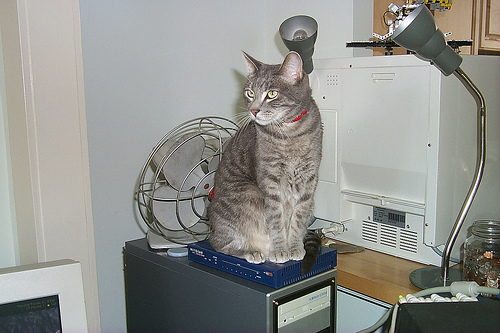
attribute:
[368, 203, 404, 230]
plate — silver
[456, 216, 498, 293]
jar — clear, glass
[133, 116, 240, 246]
fan — gray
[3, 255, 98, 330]
frame — laminated, white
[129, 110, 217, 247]
fan — small, dusty, old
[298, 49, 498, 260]
machine — large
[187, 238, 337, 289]
component — blue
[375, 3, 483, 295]
lamp — silver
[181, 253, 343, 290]
box — blue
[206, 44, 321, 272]
cat — gray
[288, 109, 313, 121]
collar — red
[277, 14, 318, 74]
lamp — gray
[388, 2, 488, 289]
lamp — gray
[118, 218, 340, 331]
computer — gray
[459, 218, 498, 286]
jar — glass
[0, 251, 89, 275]
edge — white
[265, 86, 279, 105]
eye — yellow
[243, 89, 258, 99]
eye — yellow